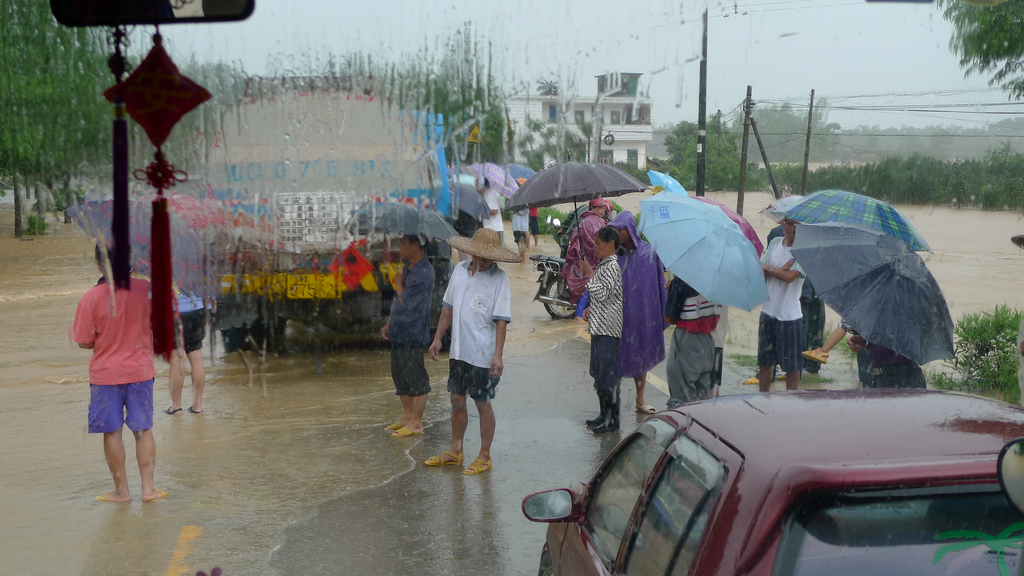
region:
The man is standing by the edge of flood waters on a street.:
[426, 200, 544, 502]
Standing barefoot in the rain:
[38, 221, 234, 525]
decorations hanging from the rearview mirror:
[89, 20, 211, 372]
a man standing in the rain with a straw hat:
[413, 201, 531, 486]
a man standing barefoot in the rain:
[72, 228, 183, 513]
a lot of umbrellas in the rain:
[359, 150, 973, 373]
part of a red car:
[515, 384, 1015, 569]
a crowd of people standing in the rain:
[344, 141, 971, 493]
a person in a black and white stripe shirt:
[580, 217, 632, 443]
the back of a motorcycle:
[521, 235, 588, 338]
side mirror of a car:
[508, 481, 607, 536]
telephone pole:
[688, 1, 724, 205]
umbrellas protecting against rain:
[514, 150, 963, 360]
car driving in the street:
[517, 394, 1015, 566]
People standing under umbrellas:
[356, 127, 955, 399]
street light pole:
[653, 0, 749, 181]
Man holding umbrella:
[48, 188, 194, 522]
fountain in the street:
[210, 96, 343, 391]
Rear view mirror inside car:
[0, 0, 346, 43]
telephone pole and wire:
[800, 65, 1010, 168]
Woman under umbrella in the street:
[557, 215, 650, 479]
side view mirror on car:
[498, 476, 584, 522]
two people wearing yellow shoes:
[356, 396, 518, 504]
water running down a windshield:
[250, 49, 440, 190]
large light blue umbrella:
[645, 185, 767, 310]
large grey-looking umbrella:
[803, 223, 974, 350]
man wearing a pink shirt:
[76, 288, 160, 383]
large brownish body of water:
[630, 191, 1022, 334]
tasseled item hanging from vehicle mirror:
[114, 29, 219, 358]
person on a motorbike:
[531, 187, 609, 321]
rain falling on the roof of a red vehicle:
[748, 381, 1017, 489]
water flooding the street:
[220, 402, 436, 558]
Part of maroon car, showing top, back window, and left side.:
[519, 417, 1016, 572]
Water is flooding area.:
[15, 286, 436, 568]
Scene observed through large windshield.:
[34, 0, 867, 472]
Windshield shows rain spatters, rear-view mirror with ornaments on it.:
[37, 3, 727, 509]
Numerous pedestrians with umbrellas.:
[360, 204, 986, 436]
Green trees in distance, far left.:
[2, 5, 132, 227]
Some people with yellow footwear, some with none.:
[92, 400, 503, 534]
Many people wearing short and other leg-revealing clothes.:
[85, 341, 806, 542]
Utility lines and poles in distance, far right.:
[669, 33, 1023, 259]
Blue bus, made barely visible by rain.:
[198, 138, 461, 417]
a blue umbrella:
[634, 184, 767, 320]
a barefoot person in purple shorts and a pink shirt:
[60, 216, 181, 508]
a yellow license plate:
[278, 260, 354, 305]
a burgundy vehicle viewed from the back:
[512, 374, 1019, 572]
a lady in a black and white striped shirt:
[568, 211, 636, 443]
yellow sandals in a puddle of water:
[414, 436, 504, 490]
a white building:
[515, 42, 670, 183]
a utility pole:
[726, 76, 766, 223]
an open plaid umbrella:
[773, 175, 932, 255]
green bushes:
[758, 142, 1016, 215]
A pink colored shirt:
[75, 279, 155, 384]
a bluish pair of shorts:
[83, 374, 157, 433]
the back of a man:
[84, 243, 154, 485]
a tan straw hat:
[450, 230, 523, 265]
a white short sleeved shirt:
[445, 265, 516, 373]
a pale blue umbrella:
[646, 183, 763, 300]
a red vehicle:
[549, 373, 1021, 567]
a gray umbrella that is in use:
[797, 211, 954, 351]